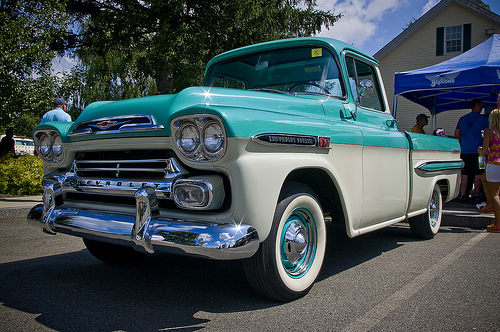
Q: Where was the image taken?
A: It was taken at the parking lot.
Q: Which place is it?
A: It is a parking lot.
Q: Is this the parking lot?
A: Yes, it is the parking lot.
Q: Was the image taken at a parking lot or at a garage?
A: It was taken at a parking lot.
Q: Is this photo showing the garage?
A: No, the picture is showing the parking lot.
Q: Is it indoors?
A: Yes, it is indoors.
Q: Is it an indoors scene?
A: Yes, it is indoors.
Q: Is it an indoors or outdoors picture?
A: It is indoors.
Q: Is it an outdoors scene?
A: No, it is indoors.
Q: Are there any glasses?
A: No, there are no glasses.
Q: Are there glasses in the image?
A: No, there are no glasses.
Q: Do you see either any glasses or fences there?
A: No, there are no glasses or fences.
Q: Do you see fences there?
A: No, there are no fences.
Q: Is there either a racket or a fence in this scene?
A: No, there are no fences or rackets.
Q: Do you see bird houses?
A: No, there are no bird houses.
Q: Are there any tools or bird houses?
A: No, there are no bird houses or tools.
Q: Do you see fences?
A: No, there are no fences.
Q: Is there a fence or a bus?
A: No, there are no fences or buses.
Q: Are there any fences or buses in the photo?
A: No, there are no fences or buses.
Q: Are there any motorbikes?
A: No, there are no motorbikes.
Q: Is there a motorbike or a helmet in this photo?
A: No, there are no motorcycles or helmets.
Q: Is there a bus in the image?
A: No, there are no buses.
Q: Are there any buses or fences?
A: No, there are no buses or fences.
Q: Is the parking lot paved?
A: Yes, the parking lot is paved.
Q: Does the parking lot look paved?
A: Yes, the parking lot is paved.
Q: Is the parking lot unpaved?
A: No, the parking lot is paved.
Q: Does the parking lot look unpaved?
A: No, the parking lot is paved.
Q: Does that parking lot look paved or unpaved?
A: The parking lot is paved.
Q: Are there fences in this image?
A: No, there are no fences.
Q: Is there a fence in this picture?
A: No, there are no fences.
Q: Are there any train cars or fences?
A: No, there are no fences or train cars.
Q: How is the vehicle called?
A: The vehicle is a car.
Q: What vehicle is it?
A: The vehicle is a car.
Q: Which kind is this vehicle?
A: This is a car.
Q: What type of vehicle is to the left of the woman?
A: The vehicle is a car.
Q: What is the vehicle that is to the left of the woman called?
A: The vehicle is a car.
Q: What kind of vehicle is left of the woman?
A: The vehicle is a car.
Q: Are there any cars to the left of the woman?
A: Yes, there is a car to the left of the woman.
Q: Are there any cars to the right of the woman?
A: No, the car is to the left of the woman.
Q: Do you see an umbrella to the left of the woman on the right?
A: No, there is a car to the left of the woman.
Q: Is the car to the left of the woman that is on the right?
A: Yes, the car is to the left of the woman.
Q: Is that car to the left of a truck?
A: No, the car is to the left of the woman.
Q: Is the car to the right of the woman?
A: No, the car is to the left of the woman.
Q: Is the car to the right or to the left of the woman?
A: The car is to the left of the woman.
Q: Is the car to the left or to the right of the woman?
A: The car is to the left of the woman.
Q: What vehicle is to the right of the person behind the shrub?
A: The vehicle is a car.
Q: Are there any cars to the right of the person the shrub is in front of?
A: Yes, there is a car to the right of the person.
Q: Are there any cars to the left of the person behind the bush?
A: No, the car is to the right of the person.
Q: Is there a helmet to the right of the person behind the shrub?
A: No, there is a car to the right of the person.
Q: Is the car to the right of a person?
A: Yes, the car is to the right of a person.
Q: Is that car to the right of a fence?
A: No, the car is to the right of a person.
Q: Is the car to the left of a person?
A: No, the car is to the right of a person.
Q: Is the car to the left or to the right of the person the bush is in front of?
A: The car is to the right of the person.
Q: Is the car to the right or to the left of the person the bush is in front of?
A: The car is to the right of the person.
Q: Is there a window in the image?
A: Yes, there is a window.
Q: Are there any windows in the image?
A: Yes, there is a window.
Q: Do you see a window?
A: Yes, there is a window.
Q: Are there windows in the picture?
A: Yes, there is a window.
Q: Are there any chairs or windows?
A: Yes, there is a window.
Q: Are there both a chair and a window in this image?
A: No, there is a window but no chairs.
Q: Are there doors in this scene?
A: No, there are no doors.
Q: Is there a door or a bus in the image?
A: No, there are no doors or buses.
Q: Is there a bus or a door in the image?
A: No, there are no doors or buses.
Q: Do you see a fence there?
A: No, there are no fences.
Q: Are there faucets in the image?
A: No, there are no faucets.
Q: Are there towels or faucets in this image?
A: No, there are no faucets or towels.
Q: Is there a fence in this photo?
A: No, there are no fences.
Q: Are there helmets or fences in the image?
A: No, there are no fences or helmets.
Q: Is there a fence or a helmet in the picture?
A: No, there are no fences or helmets.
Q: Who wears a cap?
A: The man wears a cap.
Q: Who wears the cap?
A: The man wears a cap.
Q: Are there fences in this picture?
A: No, there are no fences.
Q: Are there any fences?
A: No, there are no fences.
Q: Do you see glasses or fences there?
A: No, there are no fences or glasses.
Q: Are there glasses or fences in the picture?
A: No, there are no fences or glasses.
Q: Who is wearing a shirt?
A: The man is wearing a shirt.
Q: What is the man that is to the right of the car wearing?
A: The man is wearing a shirt.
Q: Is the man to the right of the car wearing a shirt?
A: Yes, the man is wearing a shirt.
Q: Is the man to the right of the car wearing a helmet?
A: No, the man is wearing a shirt.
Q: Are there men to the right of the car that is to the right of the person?
A: Yes, there is a man to the right of the car.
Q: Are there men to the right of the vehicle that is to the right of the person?
A: Yes, there is a man to the right of the car.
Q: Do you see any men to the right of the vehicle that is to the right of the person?
A: Yes, there is a man to the right of the car.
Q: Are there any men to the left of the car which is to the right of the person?
A: No, the man is to the right of the car.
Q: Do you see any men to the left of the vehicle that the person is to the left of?
A: No, the man is to the right of the car.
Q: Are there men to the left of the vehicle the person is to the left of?
A: No, the man is to the right of the car.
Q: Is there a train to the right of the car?
A: No, there is a man to the right of the car.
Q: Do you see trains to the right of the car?
A: No, there is a man to the right of the car.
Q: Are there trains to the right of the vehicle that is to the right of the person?
A: No, there is a man to the right of the car.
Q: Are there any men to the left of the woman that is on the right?
A: Yes, there is a man to the left of the woman.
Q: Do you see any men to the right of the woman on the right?
A: No, the man is to the left of the woman.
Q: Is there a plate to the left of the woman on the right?
A: No, there is a man to the left of the woman.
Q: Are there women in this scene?
A: Yes, there is a woman.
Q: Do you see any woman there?
A: Yes, there is a woman.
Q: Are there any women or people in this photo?
A: Yes, there is a woman.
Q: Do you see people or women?
A: Yes, there is a woman.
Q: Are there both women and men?
A: Yes, there are both a woman and a man.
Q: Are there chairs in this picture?
A: No, there are no chairs.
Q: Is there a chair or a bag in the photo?
A: No, there are no chairs or bags.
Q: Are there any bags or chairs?
A: No, there are no chairs or bags.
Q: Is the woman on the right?
A: Yes, the woman is on the right of the image.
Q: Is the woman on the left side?
A: No, the woman is on the right of the image.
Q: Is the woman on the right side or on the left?
A: The woman is on the right of the image.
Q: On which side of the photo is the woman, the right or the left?
A: The woman is on the right of the image.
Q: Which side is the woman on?
A: The woman is on the right of the image.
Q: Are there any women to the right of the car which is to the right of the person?
A: Yes, there is a woman to the right of the car.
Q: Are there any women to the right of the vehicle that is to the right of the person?
A: Yes, there is a woman to the right of the car.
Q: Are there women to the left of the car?
A: No, the woman is to the right of the car.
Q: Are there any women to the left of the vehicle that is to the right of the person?
A: No, the woman is to the right of the car.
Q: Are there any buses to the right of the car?
A: No, there is a woman to the right of the car.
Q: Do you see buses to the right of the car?
A: No, there is a woman to the right of the car.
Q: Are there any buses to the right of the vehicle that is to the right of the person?
A: No, there is a woman to the right of the car.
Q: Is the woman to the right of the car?
A: Yes, the woman is to the right of the car.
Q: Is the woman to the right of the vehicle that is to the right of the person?
A: Yes, the woman is to the right of the car.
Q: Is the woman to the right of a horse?
A: No, the woman is to the right of the car.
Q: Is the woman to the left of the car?
A: No, the woman is to the right of the car.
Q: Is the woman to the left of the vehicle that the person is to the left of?
A: No, the woman is to the right of the car.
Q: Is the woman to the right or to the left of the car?
A: The woman is to the right of the car.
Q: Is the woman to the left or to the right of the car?
A: The woman is to the right of the car.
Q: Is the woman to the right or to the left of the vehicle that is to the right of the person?
A: The woman is to the right of the car.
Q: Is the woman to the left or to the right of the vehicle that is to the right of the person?
A: The woman is to the right of the car.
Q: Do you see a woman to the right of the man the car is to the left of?
A: Yes, there is a woman to the right of the man.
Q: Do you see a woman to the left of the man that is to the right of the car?
A: No, the woman is to the right of the man.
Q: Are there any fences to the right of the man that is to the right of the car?
A: No, there is a woman to the right of the man.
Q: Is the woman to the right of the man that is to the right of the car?
A: Yes, the woman is to the right of the man.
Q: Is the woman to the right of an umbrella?
A: No, the woman is to the right of the man.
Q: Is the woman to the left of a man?
A: No, the woman is to the right of a man.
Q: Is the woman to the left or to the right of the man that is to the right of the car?
A: The woman is to the right of the man.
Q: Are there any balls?
A: No, there are no balls.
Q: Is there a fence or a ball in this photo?
A: No, there are no balls or fences.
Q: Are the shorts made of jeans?
A: Yes, the shorts are made of jeans.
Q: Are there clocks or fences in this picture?
A: No, there are no fences or clocks.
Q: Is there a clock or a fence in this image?
A: No, there are no fences or clocks.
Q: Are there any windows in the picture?
A: Yes, there is a window.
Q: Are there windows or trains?
A: Yes, there is a window.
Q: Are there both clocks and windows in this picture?
A: No, there is a window but no clocks.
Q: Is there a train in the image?
A: No, there are no trains.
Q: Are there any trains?
A: No, there are no trains.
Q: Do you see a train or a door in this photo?
A: No, there are no trains or doors.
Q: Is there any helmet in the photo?
A: No, there are no helmets.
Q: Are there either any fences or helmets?
A: No, there are no helmets or fences.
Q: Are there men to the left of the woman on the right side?
A: Yes, there is a man to the left of the woman.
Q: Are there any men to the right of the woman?
A: No, the man is to the left of the woman.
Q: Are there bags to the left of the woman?
A: No, there is a man to the left of the woman.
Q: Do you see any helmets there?
A: No, there are no helmets.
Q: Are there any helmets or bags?
A: No, there are no helmets or bags.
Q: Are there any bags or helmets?
A: No, there are no helmets or bags.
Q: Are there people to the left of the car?
A: Yes, there is a person to the left of the car.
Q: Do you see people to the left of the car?
A: Yes, there is a person to the left of the car.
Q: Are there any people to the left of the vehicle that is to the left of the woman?
A: Yes, there is a person to the left of the car.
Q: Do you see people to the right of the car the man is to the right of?
A: No, the person is to the left of the car.